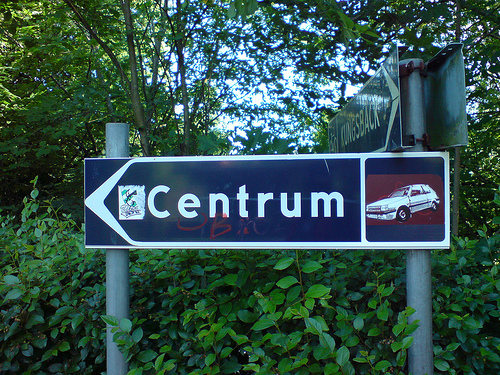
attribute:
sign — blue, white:
[76, 148, 453, 247]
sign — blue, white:
[321, 40, 472, 153]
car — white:
[365, 179, 440, 222]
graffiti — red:
[175, 201, 325, 239]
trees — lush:
[12, 1, 500, 366]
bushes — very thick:
[5, 145, 500, 360]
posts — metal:
[98, 64, 439, 372]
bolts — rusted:
[402, 58, 430, 149]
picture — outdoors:
[4, 9, 499, 362]